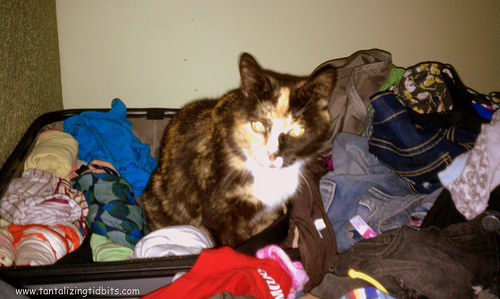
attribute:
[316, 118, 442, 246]
jeans — colored, light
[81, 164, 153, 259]
clothing — blue, green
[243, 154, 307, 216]
spot — white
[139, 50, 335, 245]
cat — white, brown, black, orange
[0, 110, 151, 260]
clothing — rolled up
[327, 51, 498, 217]
clothing — rolled up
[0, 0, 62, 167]
wall — gold, colored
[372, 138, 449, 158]
stitching — yellow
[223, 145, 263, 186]
whiskers — white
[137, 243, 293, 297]
shirt — red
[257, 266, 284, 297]
text — white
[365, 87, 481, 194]
jeans — dark, colored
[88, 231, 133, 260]
clothing — green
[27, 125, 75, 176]
clothing — yellow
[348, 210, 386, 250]
tag — small